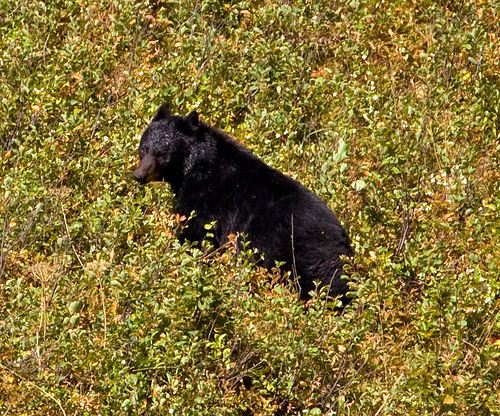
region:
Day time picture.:
[28, 40, 480, 380]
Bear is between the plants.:
[110, 101, 365, 313]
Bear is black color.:
[122, 115, 357, 305]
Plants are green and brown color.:
[32, 237, 277, 389]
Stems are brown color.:
[185, 300, 275, 387]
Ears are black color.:
[151, 100, 196, 130]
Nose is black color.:
[125, 157, 151, 192]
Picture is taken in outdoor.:
[26, 44, 453, 374]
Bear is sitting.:
[121, 105, 363, 328]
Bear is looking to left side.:
[106, 99, 226, 214]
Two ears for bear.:
[140, 90, 210, 130]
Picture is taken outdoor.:
[40, 50, 465, 395]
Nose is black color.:
[120, 150, 161, 195]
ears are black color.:
[151, 100, 205, 129]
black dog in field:
[127, 100, 351, 307]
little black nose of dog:
[133, 170, 147, 189]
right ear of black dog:
[152, 93, 173, 115]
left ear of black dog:
[185, 110, 206, 135]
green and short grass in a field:
[0, 2, 499, 414]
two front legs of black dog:
[172, 193, 212, 243]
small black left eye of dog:
[157, 152, 173, 163]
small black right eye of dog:
[135, 145, 149, 156]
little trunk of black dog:
[133, 152, 160, 182]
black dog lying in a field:
[130, 98, 352, 309]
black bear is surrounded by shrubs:
[131, 98, 358, 311]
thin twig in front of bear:
[288, 213, 300, 290]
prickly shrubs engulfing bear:
[1, 2, 499, 414]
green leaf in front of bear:
[203, 223, 210, 229]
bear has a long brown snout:
[133, 158, 155, 185]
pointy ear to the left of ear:
[156, 100, 170, 119]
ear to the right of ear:
[185, 107, 199, 125]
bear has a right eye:
[138, 145, 146, 155]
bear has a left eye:
[157, 153, 167, 163]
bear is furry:
[133, 98, 352, 307]